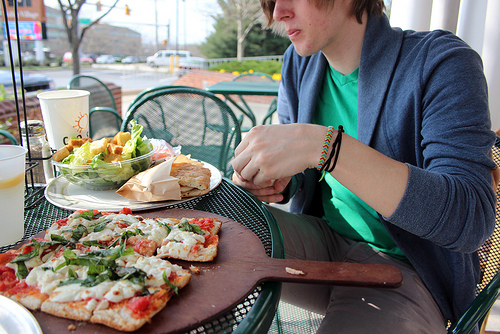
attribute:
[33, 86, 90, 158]
cup — tall, white, paper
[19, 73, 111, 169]
cup — white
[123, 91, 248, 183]
chair — green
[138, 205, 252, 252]
pizza slice — sitting by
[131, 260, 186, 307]
slice — by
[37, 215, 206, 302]
pizza — by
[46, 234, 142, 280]
veggies — green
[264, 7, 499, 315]
sweater — blue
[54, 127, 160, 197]
container — plastic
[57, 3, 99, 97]
tree — bare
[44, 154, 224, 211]
plate — white, round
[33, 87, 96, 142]
cup — paper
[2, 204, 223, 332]
pizza — slice, square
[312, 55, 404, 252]
shirt — green, colored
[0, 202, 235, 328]
pizza — slice, square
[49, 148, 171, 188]
bowl — plastic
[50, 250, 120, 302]
pizza — square, slice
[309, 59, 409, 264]
shirt — green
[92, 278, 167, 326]
slice — square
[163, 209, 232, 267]
pizza — slice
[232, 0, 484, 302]
woman — eating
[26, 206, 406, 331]
tray — wooden